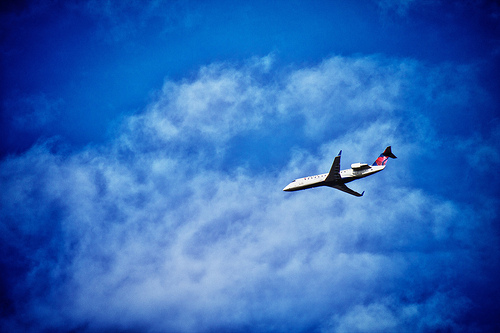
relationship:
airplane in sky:
[283, 146, 398, 200] [1, 1, 500, 333]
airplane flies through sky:
[283, 146, 398, 200] [1, 1, 500, 333]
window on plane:
[304, 178, 308, 182] [283, 146, 398, 200]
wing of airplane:
[327, 149, 341, 181] [283, 146, 398, 200]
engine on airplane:
[350, 163, 369, 170] [283, 146, 398, 200]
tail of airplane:
[372, 146, 391, 166] [283, 146, 398, 200]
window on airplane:
[306, 176, 311, 181] [283, 146, 398, 200]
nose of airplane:
[283, 184, 289, 192] [283, 146, 398, 200]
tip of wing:
[338, 150, 343, 157] [327, 149, 341, 181]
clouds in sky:
[73, 199, 492, 332] [1, 1, 500, 333]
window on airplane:
[314, 177, 318, 179] [283, 146, 398, 200]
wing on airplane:
[332, 183, 364, 197] [283, 146, 398, 200]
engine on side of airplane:
[350, 163, 369, 170] [283, 146, 398, 200]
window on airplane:
[310, 176, 314, 181] [283, 146, 398, 200]